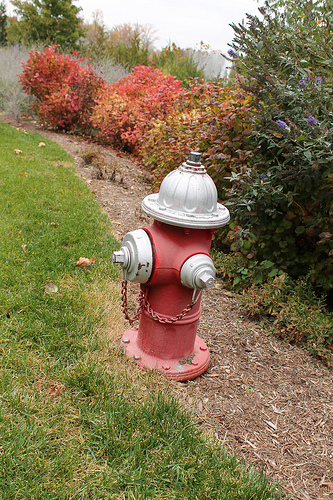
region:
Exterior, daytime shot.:
[2, 13, 321, 495]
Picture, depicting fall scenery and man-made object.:
[1, 44, 321, 496]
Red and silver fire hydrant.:
[105, 155, 227, 389]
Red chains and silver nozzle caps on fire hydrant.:
[111, 240, 214, 327]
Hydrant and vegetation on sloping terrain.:
[9, 48, 329, 485]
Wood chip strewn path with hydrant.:
[77, 145, 329, 463]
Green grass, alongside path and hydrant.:
[3, 128, 191, 496]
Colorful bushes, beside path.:
[24, 44, 228, 154]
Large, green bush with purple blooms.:
[228, 32, 329, 277]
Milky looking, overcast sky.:
[149, 12, 218, 48]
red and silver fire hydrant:
[96, 142, 248, 390]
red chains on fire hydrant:
[116, 275, 196, 330]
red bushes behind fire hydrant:
[25, 54, 186, 134]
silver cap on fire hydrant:
[113, 220, 154, 292]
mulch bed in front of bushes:
[118, 156, 267, 440]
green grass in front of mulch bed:
[7, 139, 104, 495]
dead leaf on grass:
[67, 246, 95, 277]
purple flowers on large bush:
[226, 11, 317, 187]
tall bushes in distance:
[41, 3, 215, 88]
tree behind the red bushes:
[12, 4, 97, 61]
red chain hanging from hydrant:
[115, 285, 145, 325]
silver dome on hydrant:
[146, 158, 230, 229]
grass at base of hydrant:
[109, 347, 165, 438]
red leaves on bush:
[50, 63, 157, 122]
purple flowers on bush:
[269, 104, 318, 142]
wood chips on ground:
[256, 398, 303, 443]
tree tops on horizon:
[91, 13, 163, 51]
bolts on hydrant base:
[187, 343, 208, 367]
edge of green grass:
[82, 177, 101, 219]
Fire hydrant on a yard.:
[110, 172, 238, 377]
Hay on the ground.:
[217, 347, 332, 459]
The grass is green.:
[17, 400, 128, 478]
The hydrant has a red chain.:
[118, 287, 202, 329]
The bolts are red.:
[113, 325, 220, 377]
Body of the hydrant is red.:
[149, 230, 195, 371]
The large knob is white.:
[118, 227, 156, 289]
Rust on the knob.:
[131, 256, 157, 290]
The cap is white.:
[126, 143, 243, 236]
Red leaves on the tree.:
[27, 53, 96, 126]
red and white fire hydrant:
[92, 167, 259, 406]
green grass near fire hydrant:
[36, 387, 151, 467]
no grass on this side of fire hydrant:
[132, 305, 312, 457]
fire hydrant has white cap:
[129, 144, 232, 238]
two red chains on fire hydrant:
[99, 277, 212, 324]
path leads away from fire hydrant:
[15, 85, 142, 228]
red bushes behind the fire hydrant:
[14, 34, 201, 239]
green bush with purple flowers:
[251, 91, 320, 160]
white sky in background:
[98, 6, 256, 69]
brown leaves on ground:
[5, 128, 58, 168]